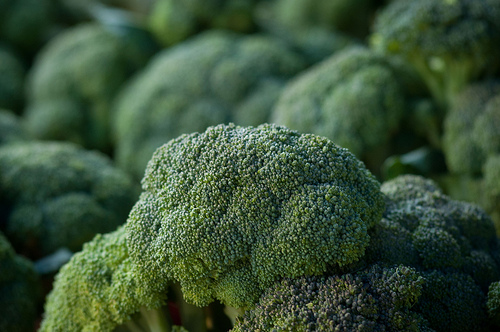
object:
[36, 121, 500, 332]
broccoli bunch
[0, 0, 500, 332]
brocolli background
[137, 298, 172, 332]
stalks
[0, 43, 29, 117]
vegetable piee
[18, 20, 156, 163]
broccoli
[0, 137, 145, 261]
piece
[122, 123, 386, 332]
vegetable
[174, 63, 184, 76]
green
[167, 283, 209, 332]
brocoli stem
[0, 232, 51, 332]
broccoli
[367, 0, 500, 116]
broccoli